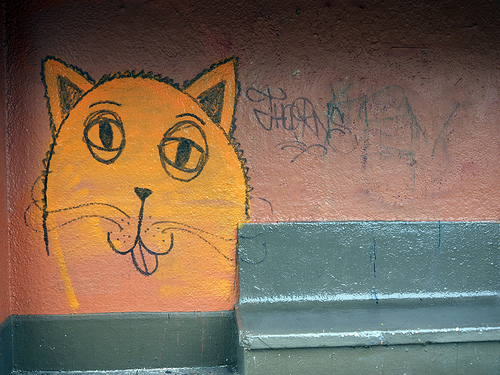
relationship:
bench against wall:
[231, 220, 498, 374] [244, 41, 472, 221]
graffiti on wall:
[26, 55, 460, 309] [1, 2, 496, 366]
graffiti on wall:
[26, 55, 460, 309] [326, 37, 470, 209]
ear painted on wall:
[38, 53, 94, 127] [9, 5, 498, 312]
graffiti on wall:
[183, 81, 497, 155] [54, 19, 492, 220]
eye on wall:
[84, 110, 124, 161] [1, 2, 496, 366]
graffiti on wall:
[26, 55, 460, 309] [9, 5, 498, 312]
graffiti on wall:
[26, 55, 460, 309] [53, 18, 495, 195]